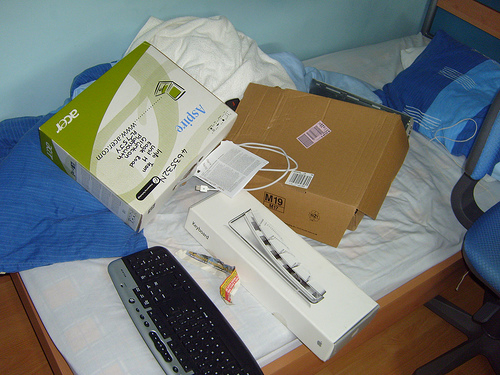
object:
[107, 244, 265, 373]
keyboard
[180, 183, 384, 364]
box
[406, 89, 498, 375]
chair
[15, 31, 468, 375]
sheets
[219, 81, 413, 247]
box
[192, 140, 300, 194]
cord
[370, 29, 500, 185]
pillow case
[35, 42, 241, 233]
boxes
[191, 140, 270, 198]
instructions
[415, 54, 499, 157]
stripes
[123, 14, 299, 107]
blanket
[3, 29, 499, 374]
bed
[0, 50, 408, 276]
comforter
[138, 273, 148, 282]
keys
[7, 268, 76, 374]
counter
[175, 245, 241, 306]
paper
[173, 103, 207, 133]
words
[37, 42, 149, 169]
area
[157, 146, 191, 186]
writing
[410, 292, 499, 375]
base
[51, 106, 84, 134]
writing